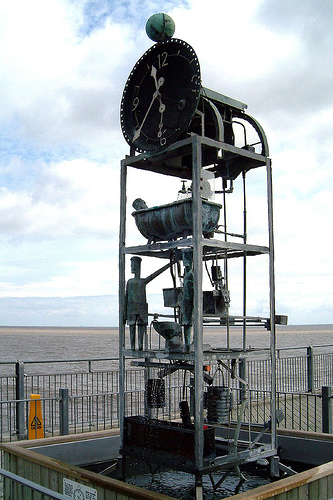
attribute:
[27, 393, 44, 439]
sign — caution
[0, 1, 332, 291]
clouds — white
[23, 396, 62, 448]
sign — yellow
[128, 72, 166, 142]
hand — long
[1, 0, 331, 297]
sky — blue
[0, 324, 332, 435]
water — blue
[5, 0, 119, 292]
clouds — white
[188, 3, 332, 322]
clouds — white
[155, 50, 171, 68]
twelve — number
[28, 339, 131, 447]
fence — grey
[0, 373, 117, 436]
fencing — steel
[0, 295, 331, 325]
water — dark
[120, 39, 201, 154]
clock — black, white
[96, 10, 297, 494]
tower — grey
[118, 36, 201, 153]
time — 11.38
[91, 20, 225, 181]
time — 11.38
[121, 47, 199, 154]
numbers — numeric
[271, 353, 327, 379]
waves — small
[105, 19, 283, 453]
tower — metal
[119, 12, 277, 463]
tower — electrical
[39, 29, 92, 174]
sky — blue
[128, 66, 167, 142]
needles — white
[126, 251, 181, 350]
man — metal